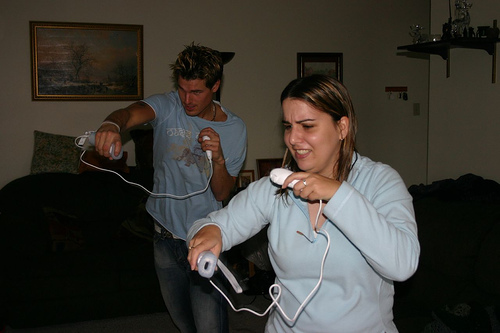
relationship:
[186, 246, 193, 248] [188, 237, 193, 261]
ring on a finger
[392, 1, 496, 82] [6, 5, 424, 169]
shelf mounted on wall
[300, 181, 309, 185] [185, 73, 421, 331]
ring on a woman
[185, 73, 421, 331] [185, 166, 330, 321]
woman holding wii mote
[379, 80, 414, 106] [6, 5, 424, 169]
key holder on wall wall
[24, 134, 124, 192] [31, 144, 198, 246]
pillow on couch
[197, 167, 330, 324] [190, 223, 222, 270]
game controller in womans hand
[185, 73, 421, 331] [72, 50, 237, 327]
woman playing a game man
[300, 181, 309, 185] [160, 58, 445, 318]
ring on woman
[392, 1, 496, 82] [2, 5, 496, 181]
shelf on wall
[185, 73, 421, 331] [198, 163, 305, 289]
woman playing game using remotes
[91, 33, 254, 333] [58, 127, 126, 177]
man hold remotes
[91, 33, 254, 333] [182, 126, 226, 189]
man hold remotes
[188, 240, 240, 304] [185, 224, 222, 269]
wii remote in hand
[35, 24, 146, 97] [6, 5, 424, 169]
picture on wall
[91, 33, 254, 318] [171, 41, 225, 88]
man has hair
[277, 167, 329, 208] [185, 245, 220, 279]
hand holding remote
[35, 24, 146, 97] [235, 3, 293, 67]
picture hanging on wall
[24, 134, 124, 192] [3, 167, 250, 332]
pillow on couch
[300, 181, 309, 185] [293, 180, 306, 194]
ring on finger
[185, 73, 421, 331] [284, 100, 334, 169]
woman has facial expression